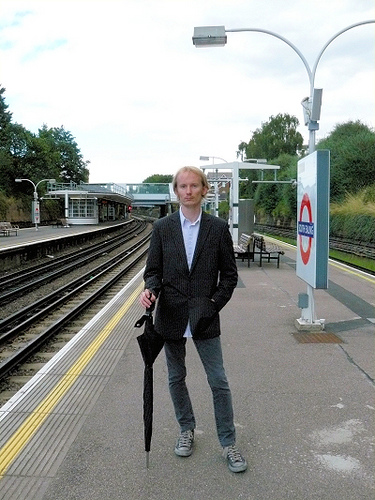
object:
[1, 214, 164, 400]
tracks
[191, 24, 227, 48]
light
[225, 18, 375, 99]
pole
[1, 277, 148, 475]
line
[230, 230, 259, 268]
bench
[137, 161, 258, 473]
man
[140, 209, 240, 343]
coat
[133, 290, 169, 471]
umbrella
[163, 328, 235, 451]
jeans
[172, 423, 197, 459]
shoes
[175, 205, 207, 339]
shirt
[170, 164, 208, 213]
head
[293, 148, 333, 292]
sign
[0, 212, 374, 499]
platform